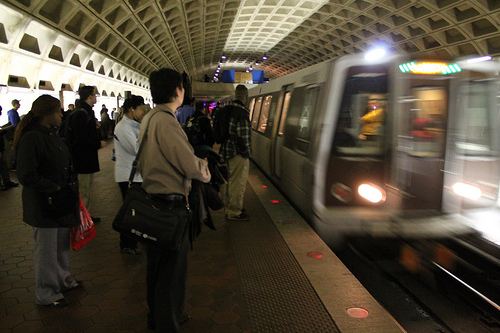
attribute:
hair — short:
[147, 62, 191, 109]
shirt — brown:
[132, 103, 217, 201]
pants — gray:
[31, 225, 76, 305]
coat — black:
[13, 124, 82, 229]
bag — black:
[118, 107, 198, 257]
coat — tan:
[136, 108, 210, 192]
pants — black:
[140, 192, 195, 330]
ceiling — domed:
[16, 1, 498, 75]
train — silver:
[245, 47, 490, 246]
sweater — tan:
[132, 104, 214, 195]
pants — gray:
[32, 217, 76, 308]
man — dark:
[218, 83, 254, 220]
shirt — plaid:
[211, 100, 255, 165]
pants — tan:
[212, 150, 251, 219]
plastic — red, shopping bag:
[72, 197, 117, 270]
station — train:
[5, 7, 494, 324]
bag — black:
[111, 186, 191, 248]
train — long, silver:
[314, 56, 480, 217]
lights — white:
[245, 50, 497, 254]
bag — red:
[67, 194, 100, 249]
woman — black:
[12, 94, 103, 295]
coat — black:
[17, 124, 88, 220]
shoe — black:
[37, 295, 68, 306]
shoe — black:
[67, 281, 81, 291]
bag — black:
[103, 166, 203, 259]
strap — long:
[131, 137, 145, 167]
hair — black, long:
[8, 92, 61, 182]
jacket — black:
[24, 130, 76, 240]